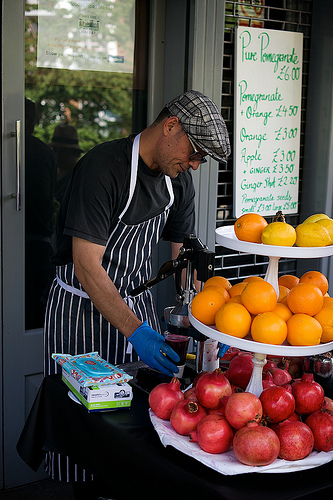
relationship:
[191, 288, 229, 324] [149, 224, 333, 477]
orange on stand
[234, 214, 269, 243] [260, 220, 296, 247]
orange near lemon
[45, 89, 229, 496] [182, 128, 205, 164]
man wearing sunglasses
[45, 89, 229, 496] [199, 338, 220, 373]
man holding cup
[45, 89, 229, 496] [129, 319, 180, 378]
man wearing glove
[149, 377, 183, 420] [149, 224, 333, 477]
pomegranate on stand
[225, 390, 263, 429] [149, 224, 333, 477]
pomegranate on stand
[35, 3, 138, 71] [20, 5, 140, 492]
menu in indow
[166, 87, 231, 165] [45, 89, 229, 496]
hat on man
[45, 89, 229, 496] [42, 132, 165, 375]
man wearing apron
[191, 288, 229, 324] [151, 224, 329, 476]
orange in container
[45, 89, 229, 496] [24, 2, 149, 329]
man in front of door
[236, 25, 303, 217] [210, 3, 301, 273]
white board on window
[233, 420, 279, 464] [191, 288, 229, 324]
pomegranate below orange